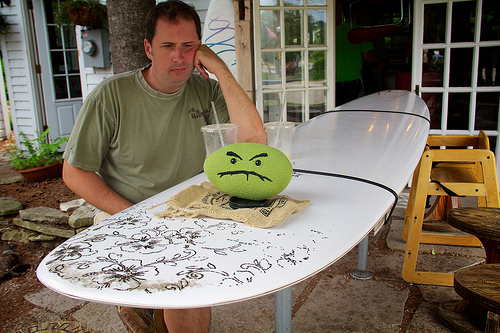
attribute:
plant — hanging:
[9, 118, 71, 173]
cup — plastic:
[261, 104, 300, 164]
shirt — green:
[63, 64, 226, 197]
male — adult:
[60, 2, 269, 202]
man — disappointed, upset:
[60, 0, 267, 329]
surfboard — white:
[203, 2, 248, 97]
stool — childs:
[393, 128, 497, 286]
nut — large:
[202, 141, 292, 198]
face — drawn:
[217, 152, 272, 182]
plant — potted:
[8, 127, 69, 184]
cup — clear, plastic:
[202, 119, 239, 172]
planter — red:
[19, 165, 52, 185]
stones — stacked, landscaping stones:
[22, 182, 79, 247]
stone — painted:
[197, 134, 299, 207]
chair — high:
[396, 130, 498, 280]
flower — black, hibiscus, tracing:
[107, 256, 152, 292]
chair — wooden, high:
[405, 135, 497, 302]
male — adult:
[61, 16, 272, 207]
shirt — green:
[90, 57, 250, 204]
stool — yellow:
[405, 132, 498, 284]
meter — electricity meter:
[75, 26, 110, 70]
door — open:
[13, 12, 96, 174]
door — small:
[22, 6, 95, 150]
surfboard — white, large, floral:
[26, 79, 435, 329]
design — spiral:
[200, 15, 241, 55]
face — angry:
[220, 146, 280, 186]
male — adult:
[78, 2, 263, 201]